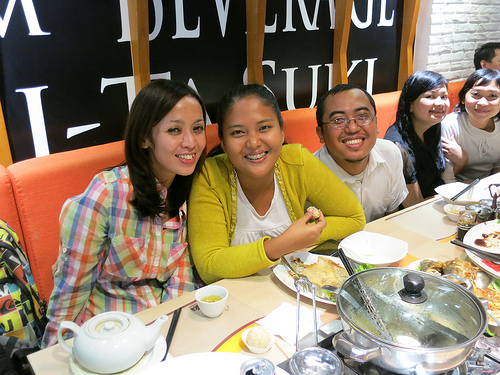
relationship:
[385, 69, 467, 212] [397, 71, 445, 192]
woman has long hair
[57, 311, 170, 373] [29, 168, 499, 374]
tea kettle on table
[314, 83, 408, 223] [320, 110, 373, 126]
man wearing glasses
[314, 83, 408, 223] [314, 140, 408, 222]
man has white shirt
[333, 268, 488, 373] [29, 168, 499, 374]
pot on table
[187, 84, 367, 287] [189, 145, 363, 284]
young woman wearing yellow sweater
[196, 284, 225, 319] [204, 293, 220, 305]
cup of soup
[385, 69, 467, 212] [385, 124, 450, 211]
woman wearing blue shirt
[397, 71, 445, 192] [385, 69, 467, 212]
hair of woman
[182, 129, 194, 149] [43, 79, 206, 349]
nose of young woman